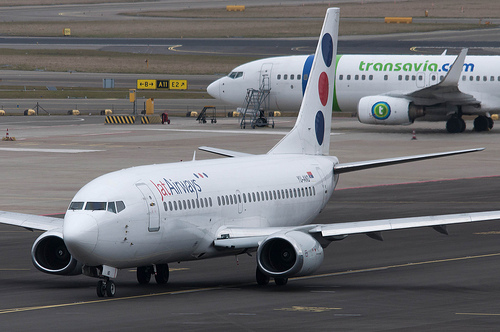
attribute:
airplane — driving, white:
[0, 6, 499, 298]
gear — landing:
[94, 277, 118, 297]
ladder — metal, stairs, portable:
[239, 86, 268, 132]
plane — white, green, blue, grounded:
[204, 52, 499, 134]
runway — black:
[1, 173, 500, 331]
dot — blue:
[320, 32, 336, 68]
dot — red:
[318, 71, 330, 107]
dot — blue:
[313, 109, 327, 145]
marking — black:
[171, 81, 185, 88]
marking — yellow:
[157, 82, 170, 87]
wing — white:
[217, 211, 498, 248]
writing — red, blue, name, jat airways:
[150, 177, 202, 200]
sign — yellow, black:
[136, 77, 192, 91]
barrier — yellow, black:
[102, 111, 162, 125]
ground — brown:
[1, 46, 271, 79]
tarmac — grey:
[1, 117, 499, 213]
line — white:
[0, 251, 499, 316]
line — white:
[456, 310, 498, 320]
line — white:
[2, 118, 84, 125]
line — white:
[168, 42, 212, 54]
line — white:
[409, 43, 460, 53]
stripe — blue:
[300, 49, 316, 96]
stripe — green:
[333, 54, 342, 112]